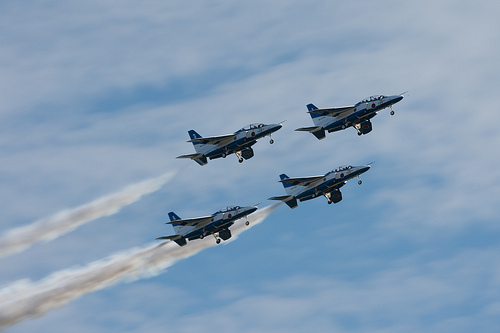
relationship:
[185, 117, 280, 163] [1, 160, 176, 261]
airplane has smoke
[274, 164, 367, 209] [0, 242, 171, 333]
airplane has smoke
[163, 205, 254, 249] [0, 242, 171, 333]
airplane has smoke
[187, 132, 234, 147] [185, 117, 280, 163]
wing of airplane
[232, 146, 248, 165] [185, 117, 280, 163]
wheel of airplane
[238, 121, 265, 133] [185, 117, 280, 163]
cockpit on airplane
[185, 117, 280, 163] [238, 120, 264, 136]
airplane has cockpit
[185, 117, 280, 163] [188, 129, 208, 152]
airplane has tail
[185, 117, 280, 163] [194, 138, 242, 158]
airplane has side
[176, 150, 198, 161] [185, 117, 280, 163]
hind wing on airplane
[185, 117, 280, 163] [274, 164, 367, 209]
airplane next to airplane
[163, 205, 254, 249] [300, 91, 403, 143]
airplane next to airplane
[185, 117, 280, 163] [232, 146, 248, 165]
airplane has wheel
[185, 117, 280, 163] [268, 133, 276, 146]
airplane has wheel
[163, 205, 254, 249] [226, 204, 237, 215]
airplane has pilot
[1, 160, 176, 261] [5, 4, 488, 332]
smoke trails in sky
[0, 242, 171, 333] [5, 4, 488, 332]
smoke trails in sky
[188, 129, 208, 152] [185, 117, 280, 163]
tail on airplane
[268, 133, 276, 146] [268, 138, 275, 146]
wheel has tire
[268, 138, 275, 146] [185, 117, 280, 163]
tire in front of airplane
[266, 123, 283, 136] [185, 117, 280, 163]
nose on front of airplane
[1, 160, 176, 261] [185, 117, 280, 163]
smoke coming from airplane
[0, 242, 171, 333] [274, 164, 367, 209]
smoke coming from airplane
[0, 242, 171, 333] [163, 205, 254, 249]
smoke coming from airplane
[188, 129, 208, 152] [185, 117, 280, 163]
tail of airplane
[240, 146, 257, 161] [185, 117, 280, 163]
landing gear under airplane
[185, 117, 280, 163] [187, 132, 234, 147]
airplane has wing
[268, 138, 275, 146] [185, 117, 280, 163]
tire under airplane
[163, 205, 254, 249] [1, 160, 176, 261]
airplane has smoke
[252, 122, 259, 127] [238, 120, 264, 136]
pilot in cockpit